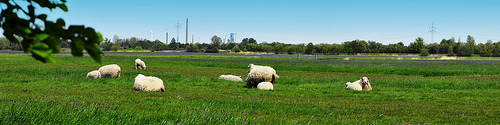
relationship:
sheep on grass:
[132, 73, 165, 92] [121, 67, 191, 105]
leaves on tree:
[350, 43, 352, 49] [341, 38, 369, 59]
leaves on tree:
[446, 45, 454, 52] [435, 38, 463, 58]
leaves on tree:
[169, 41, 175, 47] [163, 33, 200, 55]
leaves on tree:
[153, 41, 162, 47] [150, 37, 169, 51]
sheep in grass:
[241, 59, 284, 95] [0, 51, 482, 122]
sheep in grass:
[352, 76, 372, 91] [0, 51, 482, 122]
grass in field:
[386, 75, 484, 113] [5, 42, 496, 122]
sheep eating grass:
[133, 58, 146, 70] [123, 50, 244, 110]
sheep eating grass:
[98, 64, 120, 78] [123, 50, 244, 110]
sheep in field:
[338, 72, 383, 93] [5, 42, 496, 122]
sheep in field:
[237, 53, 284, 90] [5, 42, 496, 122]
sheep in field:
[122, 47, 150, 73] [5, 42, 496, 122]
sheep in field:
[90, 60, 122, 82] [5, 42, 496, 122]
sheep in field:
[126, 68, 166, 98] [5, 42, 496, 122]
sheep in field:
[81, 64, 104, 82] [5, 42, 496, 122]